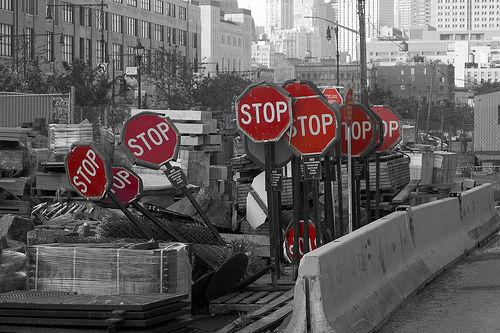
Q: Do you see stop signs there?
A: Yes, there is a stop sign.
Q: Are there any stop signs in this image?
A: Yes, there is a stop sign.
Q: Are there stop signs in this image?
A: Yes, there is a stop sign.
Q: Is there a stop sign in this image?
A: Yes, there is a stop sign.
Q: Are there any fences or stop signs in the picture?
A: Yes, there is a stop sign.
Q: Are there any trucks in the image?
A: No, there are no trucks.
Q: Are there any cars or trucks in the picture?
A: No, there are no trucks or cars.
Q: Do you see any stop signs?
A: Yes, there is a stop sign.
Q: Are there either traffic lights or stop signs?
A: Yes, there is a stop sign.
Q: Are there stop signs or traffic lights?
A: Yes, there is a stop sign.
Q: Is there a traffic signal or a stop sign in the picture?
A: Yes, there is a stop sign.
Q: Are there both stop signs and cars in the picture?
A: No, there is a stop sign but no cars.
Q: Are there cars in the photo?
A: No, there are no cars.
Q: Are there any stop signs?
A: Yes, there is a stop sign.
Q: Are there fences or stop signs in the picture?
A: Yes, there is a stop sign.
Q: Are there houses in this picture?
A: No, there are no houses.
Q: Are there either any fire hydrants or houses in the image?
A: No, there are no houses or fire hydrants.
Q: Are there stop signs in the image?
A: Yes, there is a stop sign.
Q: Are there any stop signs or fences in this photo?
A: Yes, there is a stop sign.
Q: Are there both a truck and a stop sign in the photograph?
A: No, there is a stop sign but no trucks.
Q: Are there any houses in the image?
A: No, there are no houses.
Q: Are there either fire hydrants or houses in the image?
A: No, there are no houses or fire hydrants.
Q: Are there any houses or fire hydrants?
A: No, there are no houses or fire hydrants.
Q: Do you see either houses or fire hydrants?
A: No, there are no houses or fire hydrants.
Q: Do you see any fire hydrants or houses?
A: No, there are no houses or fire hydrants.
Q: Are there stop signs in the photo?
A: Yes, there is a stop sign.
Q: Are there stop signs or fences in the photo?
A: Yes, there is a stop sign.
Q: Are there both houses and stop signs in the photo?
A: No, there is a stop sign but no houses.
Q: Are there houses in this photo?
A: No, there are no houses.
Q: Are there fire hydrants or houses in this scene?
A: No, there are no houses or fire hydrants.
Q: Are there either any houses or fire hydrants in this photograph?
A: No, there are no houses or fire hydrants.